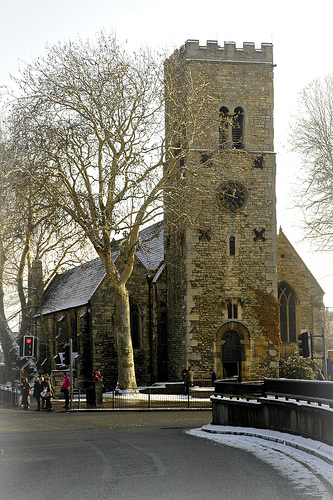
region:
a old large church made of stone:
[24, 30, 331, 410]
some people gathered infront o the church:
[19, 369, 104, 408]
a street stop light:
[16, 366, 26, 407]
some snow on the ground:
[262, 434, 320, 463]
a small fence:
[75, 382, 215, 412]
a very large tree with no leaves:
[1, 40, 242, 399]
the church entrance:
[213, 331, 254, 388]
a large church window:
[269, 281, 303, 348]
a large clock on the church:
[212, 178, 251, 210]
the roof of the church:
[25, 213, 174, 317]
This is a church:
[14, 28, 309, 394]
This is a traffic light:
[12, 323, 40, 356]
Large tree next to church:
[8, 33, 167, 415]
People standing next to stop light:
[15, 365, 84, 416]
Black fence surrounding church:
[29, 367, 221, 413]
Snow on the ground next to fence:
[200, 411, 331, 499]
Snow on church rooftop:
[19, 198, 187, 320]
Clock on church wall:
[215, 177, 251, 217]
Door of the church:
[200, 305, 269, 392]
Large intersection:
[6, 401, 257, 499]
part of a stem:
[120, 356, 130, 374]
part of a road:
[169, 441, 186, 468]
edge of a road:
[233, 438, 252, 471]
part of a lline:
[152, 450, 169, 473]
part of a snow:
[230, 426, 244, 455]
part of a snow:
[244, 435, 256, 456]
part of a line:
[149, 448, 162, 463]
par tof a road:
[151, 428, 164, 450]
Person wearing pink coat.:
[60, 376, 69, 386]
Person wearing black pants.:
[58, 392, 79, 405]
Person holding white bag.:
[37, 387, 48, 396]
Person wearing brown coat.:
[183, 373, 198, 383]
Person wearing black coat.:
[208, 369, 221, 382]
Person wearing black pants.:
[43, 394, 57, 408]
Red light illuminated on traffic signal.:
[24, 335, 36, 351]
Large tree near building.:
[97, 305, 151, 414]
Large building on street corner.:
[56, 288, 268, 390]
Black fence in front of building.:
[107, 386, 187, 410]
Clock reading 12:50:
[216, 178, 248, 212]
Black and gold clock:
[214, 177, 249, 213]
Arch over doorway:
[214, 318, 253, 380]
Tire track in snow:
[278, 437, 332, 486]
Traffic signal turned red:
[22, 336, 35, 356]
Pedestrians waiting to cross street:
[18, 372, 71, 412]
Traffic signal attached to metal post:
[294, 327, 328, 379]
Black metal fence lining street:
[70, 381, 212, 409]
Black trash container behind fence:
[83, 380, 103, 407]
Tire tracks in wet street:
[71, 436, 176, 481]